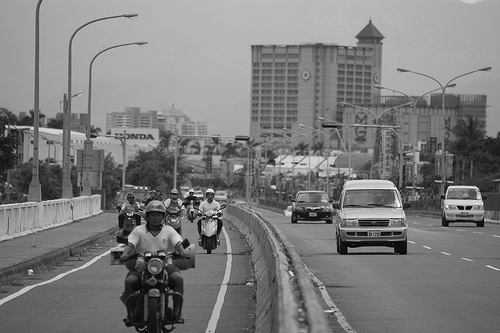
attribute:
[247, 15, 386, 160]
building — large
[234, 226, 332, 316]
barrier — concrete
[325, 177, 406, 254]
suv — white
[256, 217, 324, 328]
brarrier road — concrete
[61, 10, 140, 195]
post — tall , metal 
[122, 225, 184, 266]
pullover — white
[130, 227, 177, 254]
shirt — white 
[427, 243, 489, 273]
lines — dashed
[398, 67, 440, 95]
light — curved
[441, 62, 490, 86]
light — curved